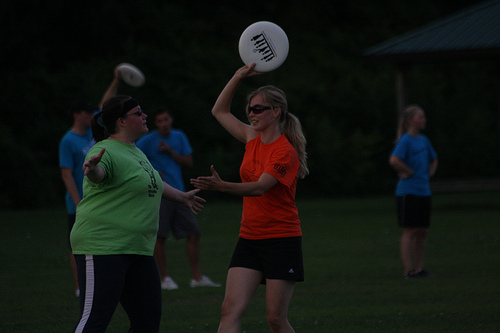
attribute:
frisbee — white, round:
[114, 60, 149, 89]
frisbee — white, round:
[235, 18, 293, 76]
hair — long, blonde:
[246, 80, 313, 182]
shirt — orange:
[232, 128, 306, 245]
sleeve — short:
[261, 143, 299, 187]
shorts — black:
[223, 229, 311, 288]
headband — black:
[100, 94, 141, 119]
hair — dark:
[84, 91, 138, 149]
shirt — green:
[65, 132, 165, 255]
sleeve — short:
[79, 143, 116, 186]